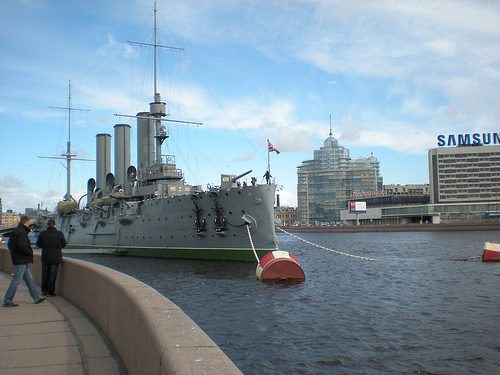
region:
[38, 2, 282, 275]
a ship anchored in water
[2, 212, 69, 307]
two men standing near a wall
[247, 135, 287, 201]
a flag on the front of a ship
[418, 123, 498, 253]
a building near the waterfront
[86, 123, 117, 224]
smokestack on a ship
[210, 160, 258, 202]
a gun turret on a ship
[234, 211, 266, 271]
a chain for an anchor on a ship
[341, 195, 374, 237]
an advertising sign near the water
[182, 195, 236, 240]
two anchors on the side of a ship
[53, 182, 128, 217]
lifeboats on the side of a ship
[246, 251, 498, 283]
Two red and white buoys in the water.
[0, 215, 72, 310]
Two men standing next to a wall.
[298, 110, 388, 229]
The white building on the other side.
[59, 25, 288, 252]
The big gray ship on the water.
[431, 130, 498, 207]
The Samsung sign on the building.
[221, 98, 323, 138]
Fluffy white clouds in the sky.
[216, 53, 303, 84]
The clear baby blue sky.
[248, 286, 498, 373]
The dark water with ripples.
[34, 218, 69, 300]
A man dressed all in black.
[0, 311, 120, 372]
The bricked sidewalk near the wall.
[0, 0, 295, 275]
A ship is in a harbor.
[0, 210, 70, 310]
Two men are looking at the ship.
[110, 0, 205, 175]
A radio tower is at the front of the ship.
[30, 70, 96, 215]
A radio tower is at the rear of the ship.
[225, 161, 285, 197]
Three people are at the front of the ship.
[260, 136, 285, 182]
A flag is at the front of the ship.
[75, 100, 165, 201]
The ship has three smokestacks.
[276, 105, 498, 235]
Two large buildings are in the background.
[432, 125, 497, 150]
The word Samsung is on top of one of the buildings.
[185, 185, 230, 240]
Two anchors are on the left side of the ship.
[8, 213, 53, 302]
Man in a black jacket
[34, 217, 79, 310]
Person standing next to a ledge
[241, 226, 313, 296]
Red and white boat anchor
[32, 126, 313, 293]
Large gray ship sitting in water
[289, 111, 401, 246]
Building next to water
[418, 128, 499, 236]
Samsung building next to water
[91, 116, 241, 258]
Smoke stacks on a ship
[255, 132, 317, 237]
Flag on the front of a ship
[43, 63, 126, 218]
Pole on a ship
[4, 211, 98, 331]
Two people looking at a ship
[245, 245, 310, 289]
red and white floating barrel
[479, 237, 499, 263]
another red and white floating barrel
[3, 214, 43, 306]
man walking on the pier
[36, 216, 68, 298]
man standing on the pier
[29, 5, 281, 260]
a large naval war ship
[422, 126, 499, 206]
a SAMSUNG building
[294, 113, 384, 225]
a tall office building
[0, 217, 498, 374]
choppy water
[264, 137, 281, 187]
the British flag flying on a war ship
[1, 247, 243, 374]
a large concrete pier